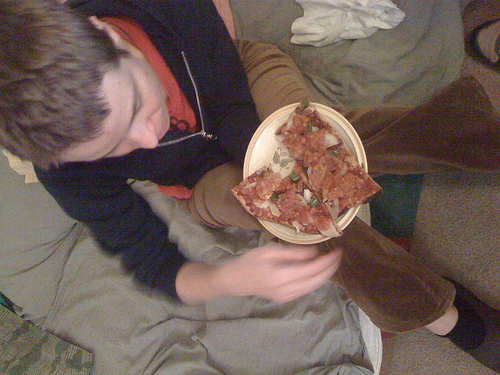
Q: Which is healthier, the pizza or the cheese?
A: The cheese is healthier than the pizza.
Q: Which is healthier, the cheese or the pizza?
A: The cheese is healthier than the pizza.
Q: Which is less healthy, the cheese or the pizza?
A: The pizza is less healthy than the cheese.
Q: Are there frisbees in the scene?
A: No, there are no frisbees.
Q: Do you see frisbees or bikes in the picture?
A: No, there are no frisbees or bikes.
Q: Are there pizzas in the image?
A: Yes, there is a pizza.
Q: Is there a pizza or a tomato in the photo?
A: Yes, there is a pizza.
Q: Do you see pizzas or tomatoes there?
A: Yes, there is a pizza.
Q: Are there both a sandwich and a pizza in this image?
A: No, there is a pizza but no sandwiches.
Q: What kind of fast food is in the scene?
A: The fast food is a pizza.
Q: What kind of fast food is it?
A: The food is a pizza.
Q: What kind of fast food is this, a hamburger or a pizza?
A: This is a pizza.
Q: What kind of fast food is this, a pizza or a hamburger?
A: This is a pizza.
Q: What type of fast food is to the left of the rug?
A: The food is a pizza.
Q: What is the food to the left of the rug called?
A: The food is a pizza.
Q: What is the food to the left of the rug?
A: The food is a pizza.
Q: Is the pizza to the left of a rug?
A: Yes, the pizza is to the left of a rug.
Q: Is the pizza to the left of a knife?
A: No, the pizza is to the left of a rug.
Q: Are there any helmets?
A: No, there are no helmets.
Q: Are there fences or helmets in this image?
A: No, there are no helmets or fences.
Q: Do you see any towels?
A: Yes, there is a towel.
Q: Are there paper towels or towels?
A: Yes, there is a towel.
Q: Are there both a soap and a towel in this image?
A: No, there is a towel but no soaps.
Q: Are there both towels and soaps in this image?
A: No, there is a towel but no soaps.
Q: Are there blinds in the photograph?
A: No, there are no blinds.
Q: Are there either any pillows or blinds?
A: No, there are no blinds or pillows.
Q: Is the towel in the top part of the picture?
A: Yes, the towel is in the top of the image.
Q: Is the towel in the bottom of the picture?
A: No, the towel is in the top of the image.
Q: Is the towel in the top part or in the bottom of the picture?
A: The towel is in the top of the image.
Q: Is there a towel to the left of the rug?
A: Yes, there is a towel to the left of the rug.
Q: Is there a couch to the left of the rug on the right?
A: No, there is a towel to the left of the rug.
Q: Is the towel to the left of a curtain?
A: No, the towel is to the left of the rug.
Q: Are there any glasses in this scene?
A: No, there are no glasses.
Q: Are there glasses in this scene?
A: No, there are no glasses.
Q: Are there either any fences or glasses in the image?
A: No, there are no glasses or fences.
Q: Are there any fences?
A: No, there are no fences.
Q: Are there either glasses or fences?
A: No, there are no fences or glasses.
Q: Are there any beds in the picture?
A: Yes, there is a bed.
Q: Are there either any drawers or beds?
A: Yes, there is a bed.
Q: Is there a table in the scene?
A: No, there are no tables.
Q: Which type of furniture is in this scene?
A: The furniture is a bed.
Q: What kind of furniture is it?
A: The piece of furniture is a bed.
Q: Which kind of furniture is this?
A: This is a bed.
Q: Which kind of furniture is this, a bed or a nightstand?
A: This is a bed.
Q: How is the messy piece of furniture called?
A: The piece of furniture is a bed.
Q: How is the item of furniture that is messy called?
A: The piece of furniture is a bed.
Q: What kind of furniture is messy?
A: The furniture is a bed.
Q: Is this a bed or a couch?
A: This is a bed.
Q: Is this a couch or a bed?
A: This is a bed.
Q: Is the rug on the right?
A: Yes, the rug is on the right of the image.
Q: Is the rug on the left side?
A: No, the rug is on the right of the image.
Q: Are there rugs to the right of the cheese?
A: Yes, there is a rug to the right of the cheese.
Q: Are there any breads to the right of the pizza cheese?
A: No, there is a rug to the right of the cheese.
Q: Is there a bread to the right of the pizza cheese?
A: No, there is a rug to the right of the cheese.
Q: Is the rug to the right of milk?
A: No, the rug is to the right of the cheese.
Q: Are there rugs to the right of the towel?
A: Yes, there is a rug to the right of the towel.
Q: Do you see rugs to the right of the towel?
A: Yes, there is a rug to the right of the towel.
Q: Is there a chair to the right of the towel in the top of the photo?
A: No, there is a rug to the right of the towel.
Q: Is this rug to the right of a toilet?
A: No, the rug is to the right of the towel.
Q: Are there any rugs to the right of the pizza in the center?
A: Yes, there is a rug to the right of the pizza.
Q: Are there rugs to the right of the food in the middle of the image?
A: Yes, there is a rug to the right of the pizza.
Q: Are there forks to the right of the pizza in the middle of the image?
A: No, there is a rug to the right of the pizza.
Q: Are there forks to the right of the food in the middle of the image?
A: No, there is a rug to the right of the pizza.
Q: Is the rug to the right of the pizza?
A: Yes, the rug is to the right of the pizza.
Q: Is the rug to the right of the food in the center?
A: Yes, the rug is to the right of the pizza.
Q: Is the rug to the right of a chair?
A: No, the rug is to the right of the pizza.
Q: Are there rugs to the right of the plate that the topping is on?
A: Yes, there is a rug to the right of the plate.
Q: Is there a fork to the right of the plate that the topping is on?
A: No, there is a rug to the right of the plate.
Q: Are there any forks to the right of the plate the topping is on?
A: No, there is a rug to the right of the plate.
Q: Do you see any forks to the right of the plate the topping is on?
A: No, there is a rug to the right of the plate.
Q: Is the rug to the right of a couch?
A: No, the rug is to the right of a plate.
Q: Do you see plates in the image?
A: Yes, there is a plate.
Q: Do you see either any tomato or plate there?
A: Yes, there is a plate.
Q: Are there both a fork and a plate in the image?
A: No, there is a plate but no forks.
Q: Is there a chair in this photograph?
A: No, there are no chairs.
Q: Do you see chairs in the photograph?
A: No, there are no chairs.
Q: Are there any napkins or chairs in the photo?
A: No, there are no chairs or napkins.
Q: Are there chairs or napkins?
A: No, there are no chairs or napkins.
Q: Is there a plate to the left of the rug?
A: Yes, there is a plate to the left of the rug.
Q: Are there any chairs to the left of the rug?
A: No, there is a plate to the left of the rug.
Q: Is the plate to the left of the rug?
A: Yes, the plate is to the left of the rug.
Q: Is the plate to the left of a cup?
A: No, the plate is to the left of the rug.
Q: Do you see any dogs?
A: No, there are no dogs.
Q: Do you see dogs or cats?
A: No, there are no dogs or cats.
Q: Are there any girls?
A: No, there are no girls.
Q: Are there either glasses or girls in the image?
A: No, there are no girls or glasses.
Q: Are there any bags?
A: No, there are no bags.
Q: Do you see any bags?
A: No, there are no bags.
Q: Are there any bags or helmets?
A: No, there are no bags or helmets.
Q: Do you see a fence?
A: No, there are no fences.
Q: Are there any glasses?
A: No, there are no glasses.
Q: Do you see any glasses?
A: No, there are no glasses.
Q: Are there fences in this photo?
A: No, there are no fences.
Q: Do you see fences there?
A: No, there are no fences.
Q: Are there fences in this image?
A: No, there are no fences.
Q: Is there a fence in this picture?
A: No, there are no fences.